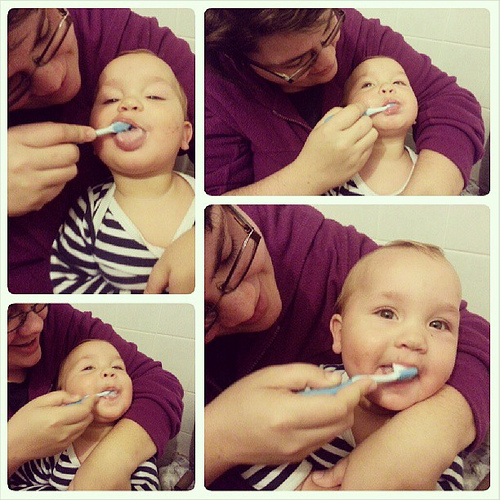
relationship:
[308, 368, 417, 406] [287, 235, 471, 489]
brush near baby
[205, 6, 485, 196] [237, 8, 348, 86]
woman with spectacles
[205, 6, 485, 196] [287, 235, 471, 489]
woman holds baby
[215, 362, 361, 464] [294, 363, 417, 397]
hand holding brush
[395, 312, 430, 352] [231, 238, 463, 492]
nose of baby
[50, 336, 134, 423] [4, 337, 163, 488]
face of baby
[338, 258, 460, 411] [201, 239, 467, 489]
face of boy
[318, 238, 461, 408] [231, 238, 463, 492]
face of baby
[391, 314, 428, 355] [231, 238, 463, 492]
nose of baby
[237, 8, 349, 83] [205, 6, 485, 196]
spectacles of woman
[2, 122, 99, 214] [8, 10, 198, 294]
hand of woman